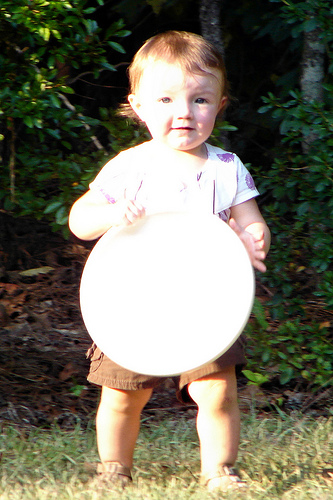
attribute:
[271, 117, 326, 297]
leaves — green, short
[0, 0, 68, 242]
leaves — green, short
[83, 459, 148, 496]
shoes — brown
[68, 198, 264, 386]
frisbee — white, round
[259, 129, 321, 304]
grass — tall, green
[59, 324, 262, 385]
shorts — brown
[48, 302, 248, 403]
short — brown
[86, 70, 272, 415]
baby shorts — brown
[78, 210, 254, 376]
frisbee — white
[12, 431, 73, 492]
grass — green, short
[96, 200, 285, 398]
frisbee — white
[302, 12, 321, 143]
trunk — brown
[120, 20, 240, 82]
hair — brown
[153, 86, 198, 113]
eyes — blue